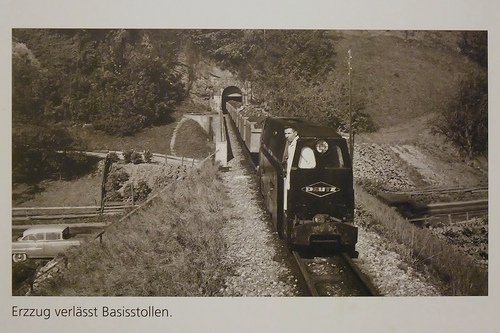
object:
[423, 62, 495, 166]
tree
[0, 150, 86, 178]
tree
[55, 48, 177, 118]
tree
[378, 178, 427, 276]
shrubs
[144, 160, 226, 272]
shrubs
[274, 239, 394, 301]
tracks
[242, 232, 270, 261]
rocks